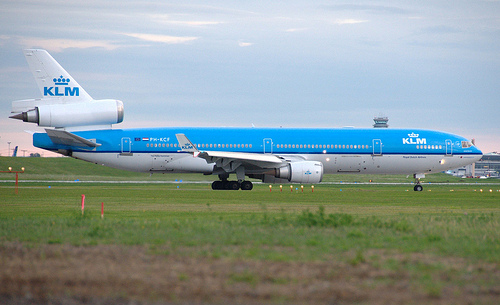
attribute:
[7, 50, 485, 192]
jet — blue, white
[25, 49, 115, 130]
tail — white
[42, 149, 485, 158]
stripe — blue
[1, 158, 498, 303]
grass — green, brown, short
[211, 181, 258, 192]
wheels — down, small, black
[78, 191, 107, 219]
markers — red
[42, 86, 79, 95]
writing — blue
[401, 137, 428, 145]
writing — white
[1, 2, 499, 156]
sky — gray, blue, clear, cloudy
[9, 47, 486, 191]
plane — parked, streamlines, blue, white, large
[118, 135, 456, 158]
doors — closed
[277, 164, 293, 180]
fan — white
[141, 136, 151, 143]
flag — small, red, white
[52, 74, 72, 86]
crown — blue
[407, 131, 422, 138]
crown — white